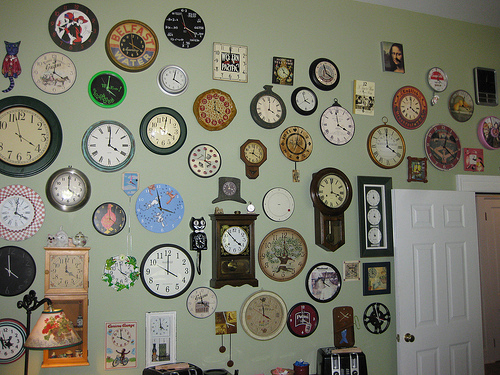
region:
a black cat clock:
[189, 215, 207, 271]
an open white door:
[388, 173, 499, 373]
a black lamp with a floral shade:
[15, 290, 83, 373]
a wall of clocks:
[1, 25, 496, 374]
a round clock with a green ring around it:
[140, 105, 187, 155]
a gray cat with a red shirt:
[0, 38, 25, 95]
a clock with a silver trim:
[157, 63, 189, 95]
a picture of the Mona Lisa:
[380, 40, 405, 73]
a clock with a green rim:
[86, 67, 126, 108]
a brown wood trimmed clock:
[238, 138, 266, 181]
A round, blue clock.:
[129, 177, 184, 233]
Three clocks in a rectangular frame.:
[358, 175, 390, 262]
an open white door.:
[389, 176, 499, 368]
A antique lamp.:
[13, 282, 85, 373]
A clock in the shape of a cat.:
[2, 35, 22, 95]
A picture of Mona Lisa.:
[379, 38, 404, 75]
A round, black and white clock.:
[160, 5, 208, 49]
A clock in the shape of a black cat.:
[185, 215, 211, 280]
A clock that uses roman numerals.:
[80, 117, 135, 174]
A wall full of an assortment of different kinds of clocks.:
[5, 7, 481, 367]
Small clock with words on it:
[105, 18, 158, 70]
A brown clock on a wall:
[310, 166, 352, 250]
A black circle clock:
[143, 244, 193, 296]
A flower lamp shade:
[23, 308, 80, 348]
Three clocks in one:
[355, 173, 391, 257]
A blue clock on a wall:
[135, 183, 182, 230]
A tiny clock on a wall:
[185, 285, 217, 315]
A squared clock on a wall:
[212, 310, 236, 367]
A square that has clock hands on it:
[406, 155, 427, 183]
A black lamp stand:
[15, 289, 50, 374]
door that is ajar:
[383, 185, 488, 366]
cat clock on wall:
[184, 215, 207, 270]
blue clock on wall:
[131, 185, 182, 230]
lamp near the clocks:
[13, 296, 78, 372]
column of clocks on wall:
[354, 170, 391, 252]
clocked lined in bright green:
[83, 68, 130, 107]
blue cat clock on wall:
[1, 25, 24, 94]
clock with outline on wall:
[364, 303, 387, 337]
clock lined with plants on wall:
[99, 253, 141, 291]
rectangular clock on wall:
[143, 313, 183, 364]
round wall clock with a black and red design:
[48, 1, 101, 54]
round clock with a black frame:
[1, 92, 64, 179]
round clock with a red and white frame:
[0, 182, 47, 245]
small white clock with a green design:
[98, 252, 141, 293]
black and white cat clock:
[186, 212, 212, 274]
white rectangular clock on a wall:
[143, 308, 182, 367]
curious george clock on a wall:
[103, 320, 141, 369]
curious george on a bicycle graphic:
[108, 345, 133, 367]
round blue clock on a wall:
[133, 181, 187, 233]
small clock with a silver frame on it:
[156, 64, 191, 96]